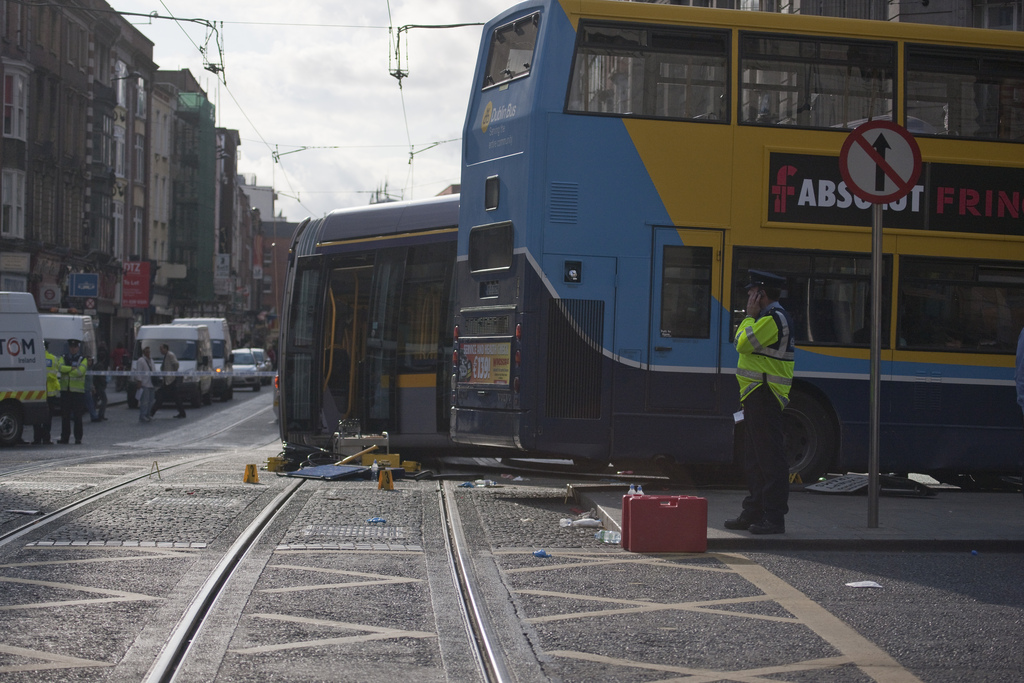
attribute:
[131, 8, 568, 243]
sky — light-blue, cloudy, white, vast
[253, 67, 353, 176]
clouds — white 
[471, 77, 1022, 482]
bus — yellow, blue, double decker, long, tall, horizontal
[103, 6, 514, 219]
sky — blue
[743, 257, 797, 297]
hat — black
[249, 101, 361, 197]
clouds — white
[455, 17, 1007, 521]
bus — yellow, blue, double decker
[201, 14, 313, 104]
sky — cloudy, vast, light-blue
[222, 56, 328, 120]
clouds — white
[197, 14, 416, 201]
sky — blue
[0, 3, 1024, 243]
sky — blue